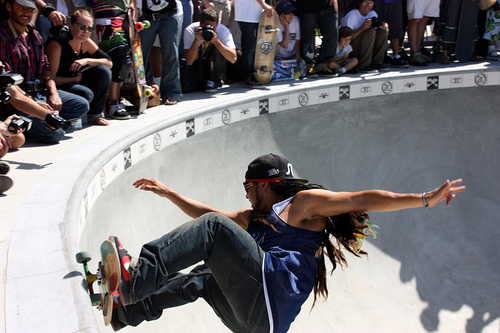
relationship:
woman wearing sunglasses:
[40, 21, 138, 106] [72, 20, 96, 30]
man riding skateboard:
[137, 172, 349, 319] [75, 239, 118, 329]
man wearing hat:
[141, 151, 386, 302] [259, 139, 341, 194]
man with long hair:
[213, 146, 330, 283] [325, 212, 372, 261]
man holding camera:
[180, 5, 237, 92] [196, 22, 215, 42]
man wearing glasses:
[87, 126, 466, 329] [234, 172, 266, 194]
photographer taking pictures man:
[180, 15, 240, 85] [89, 140, 479, 330]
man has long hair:
[107, 150, 468, 331] [259, 173, 376, 308]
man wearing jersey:
[141, 151, 386, 302] [241, 201, 347, 328]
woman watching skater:
[40, 21, 138, 106] [64, 148, 459, 327]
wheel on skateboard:
[71, 237, 121, 315] [86, 238, 144, 329]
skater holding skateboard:
[64, 148, 459, 327] [96, 220, 157, 315]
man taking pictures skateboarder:
[180, 5, 237, 92] [78, 140, 465, 328]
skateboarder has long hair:
[109, 151, 466, 331] [259, 173, 376, 308]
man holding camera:
[321, 3, 397, 70] [363, 11, 388, 26]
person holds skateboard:
[233, 0, 273, 87] [257, 7, 276, 84]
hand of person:
[420, 172, 470, 213] [118, 149, 481, 331]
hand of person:
[128, 173, 171, 198] [118, 149, 481, 331]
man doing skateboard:
[107, 150, 468, 331] [74, 237, 124, 327]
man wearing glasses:
[107, 150, 468, 331] [235, 178, 265, 193]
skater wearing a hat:
[103, 151, 465, 331] [243, 139, 310, 186]